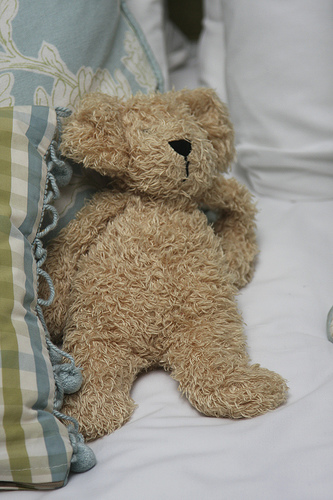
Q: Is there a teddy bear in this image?
A: Yes, there is a teddy bear.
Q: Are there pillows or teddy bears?
A: Yes, there is a teddy bear.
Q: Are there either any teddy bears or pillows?
A: Yes, there is a teddy bear.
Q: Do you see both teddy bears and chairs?
A: No, there is a teddy bear but no chairs.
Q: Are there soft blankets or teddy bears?
A: Yes, there is a soft teddy bear.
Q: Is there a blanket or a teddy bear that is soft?
A: Yes, the teddy bear is soft.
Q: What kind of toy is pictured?
A: The toy is a teddy bear.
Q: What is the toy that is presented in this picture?
A: The toy is a teddy bear.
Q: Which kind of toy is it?
A: The toy is a teddy bear.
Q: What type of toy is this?
A: This is a teddy bear.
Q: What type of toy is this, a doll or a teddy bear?
A: This is a teddy bear.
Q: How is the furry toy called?
A: The toy is a teddy bear.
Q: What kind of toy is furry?
A: The toy is a teddy bear.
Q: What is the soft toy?
A: The toy is a teddy bear.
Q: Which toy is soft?
A: The toy is a teddy bear.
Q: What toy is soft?
A: The toy is a teddy bear.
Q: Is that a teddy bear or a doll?
A: That is a teddy bear.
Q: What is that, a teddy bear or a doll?
A: That is a teddy bear.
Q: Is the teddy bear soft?
A: Yes, the teddy bear is soft.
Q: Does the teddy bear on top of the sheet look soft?
A: Yes, the teddy bear is soft.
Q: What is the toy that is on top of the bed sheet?
A: The toy is a teddy bear.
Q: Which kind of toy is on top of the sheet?
A: The toy is a teddy bear.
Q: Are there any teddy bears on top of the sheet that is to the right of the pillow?
A: Yes, there is a teddy bear on top of the bed sheet.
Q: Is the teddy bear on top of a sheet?
A: Yes, the teddy bear is on top of a sheet.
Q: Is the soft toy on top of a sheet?
A: Yes, the teddy bear is on top of a sheet.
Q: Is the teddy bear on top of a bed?
A: No, the teddy bear is on top of a sheet.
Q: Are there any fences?
A: No, there are no fences.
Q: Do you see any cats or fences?
A: No, there are no fences or cats.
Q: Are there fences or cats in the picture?
A: No, there are no fences or cats.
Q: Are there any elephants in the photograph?
A: No, there are no elephants.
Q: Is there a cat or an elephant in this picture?
A: No, there are no elephants or cats.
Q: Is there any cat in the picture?
A: No, there are no cats.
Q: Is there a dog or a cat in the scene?
A: No, there are no cats or dogs.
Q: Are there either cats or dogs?
A: No, there are no cats or dogs.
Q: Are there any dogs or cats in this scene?
A: No, there are no cats or dogs.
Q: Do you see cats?
A: No, there are no cats.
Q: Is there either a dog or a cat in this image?
A: No, there are no cats or dogs.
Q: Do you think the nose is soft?
A: Yes, the nose is soft.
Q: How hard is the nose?
A: The nose is soft.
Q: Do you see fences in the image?
A: No, there are no fences.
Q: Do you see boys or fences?
A: No, there are no fences or boys.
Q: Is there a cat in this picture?
A: No, there are no cats.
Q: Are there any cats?
A: No, there are no cats.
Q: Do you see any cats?
A: No, there are no cats.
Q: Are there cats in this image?
A: No, there are no cats.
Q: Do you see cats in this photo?
A: No, there are no cats.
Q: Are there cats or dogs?
A: No, there are no cats or dogs.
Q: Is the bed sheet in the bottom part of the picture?
A: Yes, the bed sheet is in the bottom of the image.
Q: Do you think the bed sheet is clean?
A: Yes, the bed sheet is clean.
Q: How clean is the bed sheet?
A: The bed sheet is clean.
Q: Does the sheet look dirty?
A: No, the sheet is clean.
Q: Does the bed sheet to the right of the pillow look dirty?
A: No, the bed sheet is clean.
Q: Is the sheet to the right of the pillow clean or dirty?
A: The bed sheet is clean.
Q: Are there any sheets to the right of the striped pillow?
A: Yes, there is a sheet to the right of the pillow.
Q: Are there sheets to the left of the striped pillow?
A: No, the sheet is to the right of the pillow.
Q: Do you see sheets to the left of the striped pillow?
A: No, the sheet is to the right of the pillow.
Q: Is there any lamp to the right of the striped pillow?
A: No, there is a sheet to the right of the pillow.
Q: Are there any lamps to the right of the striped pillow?
A: No, there is a sheet to the right of the pillow.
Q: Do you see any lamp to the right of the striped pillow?
A: No, there is a sheet to the right of the pillow.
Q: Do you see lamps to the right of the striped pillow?
A: No, there is a sheet to the right of the pillow.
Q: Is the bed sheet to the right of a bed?
A: No, the bed sheet is to the right of a pillow.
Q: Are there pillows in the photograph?
A: Yes, there is a pillow.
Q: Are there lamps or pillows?
A: Yes, there is a pillow.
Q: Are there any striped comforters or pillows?
A: Yes, there is a striped pillow.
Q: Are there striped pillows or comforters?
A: Yes, there is a striped pillow.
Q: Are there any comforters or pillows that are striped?
A: Yes, the pillow is striped.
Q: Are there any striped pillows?
A: Yes, there is a striped pillow.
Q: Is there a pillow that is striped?
A: Yes, there is a pillow that is striped.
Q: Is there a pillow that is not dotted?
A: Yes, there is a striped pillow.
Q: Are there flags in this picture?
A: No, there are no flags.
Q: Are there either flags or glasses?
A: No, there are no flags or glasses.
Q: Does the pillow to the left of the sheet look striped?
A: Yes, the pillow is striped.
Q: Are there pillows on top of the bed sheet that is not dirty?
A: Yes, there is a pillow on top of the sheet.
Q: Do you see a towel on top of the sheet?
A: No, there is a pillow on top of the sheet.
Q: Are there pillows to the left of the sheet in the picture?
A: Yes, there is a pillow to the left of the sheet.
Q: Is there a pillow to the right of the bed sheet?
A: No, the pillow is to the left of the bed sheet.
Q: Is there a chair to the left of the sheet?
A: No, there is a pillow to the left of the sheet.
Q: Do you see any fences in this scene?
A: No, there are no fences.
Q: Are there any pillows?
A: Yes, there is a pillow.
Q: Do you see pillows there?
A: Yes, there is a pillow.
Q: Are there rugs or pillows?
A: Yes, there is a pillow.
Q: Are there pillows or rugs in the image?
A: Yes, there is a pillow.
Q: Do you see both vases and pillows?
A: No, there is a pillow but no vases.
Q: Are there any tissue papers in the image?
A: No, there are no tissue papers.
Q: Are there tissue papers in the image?
A: No, there are no tissue papers.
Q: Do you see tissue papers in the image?
A: No, there are no tissue papers.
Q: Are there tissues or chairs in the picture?
A: No, there are no tissues or chairs.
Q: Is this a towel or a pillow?
A: This is a pillow.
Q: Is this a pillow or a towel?
A: This is a pillow.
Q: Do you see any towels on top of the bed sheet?
A: No, there is a pillow on top of the bed sheet.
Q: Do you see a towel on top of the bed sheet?
A: No, there is a pillow on top of the bed sheet.